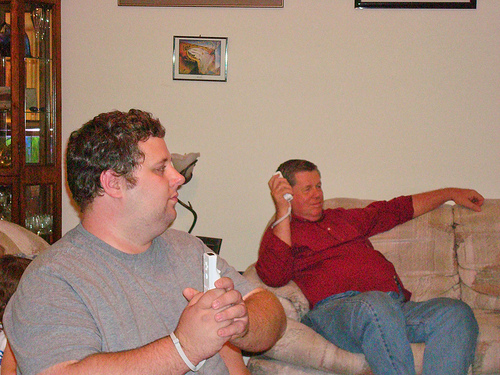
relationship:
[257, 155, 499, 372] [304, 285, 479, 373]
man with blue jeans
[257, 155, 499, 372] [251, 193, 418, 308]
man with red shirt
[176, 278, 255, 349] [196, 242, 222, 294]
hands holding controller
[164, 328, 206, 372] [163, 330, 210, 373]
bracelet on wrist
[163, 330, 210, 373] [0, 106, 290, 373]
wrist of man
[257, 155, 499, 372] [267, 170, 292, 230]
man holding remote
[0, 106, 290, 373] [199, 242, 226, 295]
man holding controllers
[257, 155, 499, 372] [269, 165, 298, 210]
man holding controllers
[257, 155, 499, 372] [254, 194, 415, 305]
man wearing red shirt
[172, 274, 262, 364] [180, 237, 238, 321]
hands holding controller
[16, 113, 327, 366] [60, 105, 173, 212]
man with hair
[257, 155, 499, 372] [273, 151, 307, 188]
man with hair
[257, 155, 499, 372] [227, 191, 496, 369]
man sitting on couch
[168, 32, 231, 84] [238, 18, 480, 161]
picture on wall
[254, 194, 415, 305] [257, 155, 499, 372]
red shirt of man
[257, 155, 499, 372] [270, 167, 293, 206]
man holding controller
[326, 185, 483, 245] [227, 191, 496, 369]
arm on couch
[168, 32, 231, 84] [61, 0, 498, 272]
picture on wall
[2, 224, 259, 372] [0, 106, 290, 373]
shirt of man